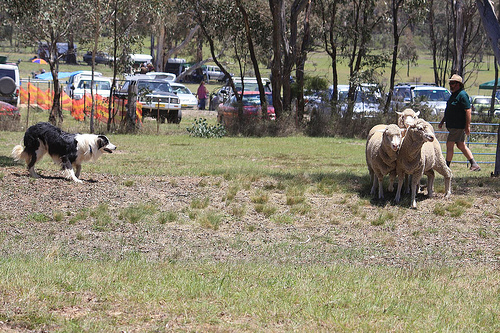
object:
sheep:
[364, 120, 403, 204]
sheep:
[400, 119, 456, 208]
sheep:
[392, 106, 419, 126]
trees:
[0, 12, 500, 139]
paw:
[65, 171, 83, 185]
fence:
[10, 78, 163, 135]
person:
[191, 75, 213, 114]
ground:
[1, 128, 497, 331]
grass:
[0, 105, 500, 333]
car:
[393, 81, 455, 126]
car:
[297, 86, 376, 136]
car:
[215, 90, 280, 130]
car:
[127, 79, 184, 122]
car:
[66, 71, 114, 101]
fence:
[423, 120, 497, 163]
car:
[169, 78, 199, 113]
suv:
[0, 64, 23, 124]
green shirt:
[442, 89, 472, 129]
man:
[439, 74, 481, 171]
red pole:
[193, 199, 315, 331]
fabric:
[22, 81, 145, 128]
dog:
[9, 122, 119, 184]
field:
[1, 50, 500, 329]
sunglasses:
[447, 78, 465, 86]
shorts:
[440, 119, 476, 149]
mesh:
[12, 86, 140, 126]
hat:
[437, 72, 472, 90]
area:
[0, 135, 500, 333]